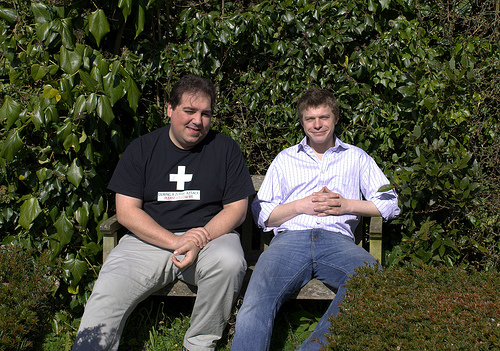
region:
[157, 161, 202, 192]
cross on mans shirt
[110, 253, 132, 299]
man wearing light grey jeans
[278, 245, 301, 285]
man wearing light blue jeans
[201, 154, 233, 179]
man wearing blue shirt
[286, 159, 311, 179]
man wearing striped shirt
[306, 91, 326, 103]
man hair is brown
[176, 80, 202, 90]
man hair is black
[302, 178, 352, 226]
mans hands are folded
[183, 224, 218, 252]
mans hand on wrist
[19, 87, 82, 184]
trees surronding men on bench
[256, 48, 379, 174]
man with short dark hair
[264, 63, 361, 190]
man with striped dress shirt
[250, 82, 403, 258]
man with his fingers crossed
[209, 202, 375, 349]
man wearing blue jeans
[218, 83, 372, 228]
man wearing a big smile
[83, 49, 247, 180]
man with his eyes closed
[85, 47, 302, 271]
man wearing a black tee shirt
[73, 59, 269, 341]
man holding his wrist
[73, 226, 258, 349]
man wearing gray pants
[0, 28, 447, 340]
several green shrubs in the background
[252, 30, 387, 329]
a man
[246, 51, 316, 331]
a man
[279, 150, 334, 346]
a man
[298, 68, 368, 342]
a man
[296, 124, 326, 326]
a man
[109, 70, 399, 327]
Two men sitting on bench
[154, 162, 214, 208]
Cross and line are white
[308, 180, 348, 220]
Hands are classed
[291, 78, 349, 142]
Face is grimacing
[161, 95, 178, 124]
Right ear is white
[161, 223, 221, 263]
Holding left wrist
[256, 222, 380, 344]
Jeans are blue and faded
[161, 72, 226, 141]
Man's face is white and pudgy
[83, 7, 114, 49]
Leaf is green and pointy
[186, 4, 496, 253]
Bush in background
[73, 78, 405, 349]
two men sitting on a bench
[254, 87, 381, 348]
man folding his hands on his belly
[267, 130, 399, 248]
man wearing a white shirt with blue stripes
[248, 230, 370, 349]
blue jeans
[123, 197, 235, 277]
man holding his wrist with his hand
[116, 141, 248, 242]
man wearing a black shirt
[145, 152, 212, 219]
white logo of a cross on a black shirt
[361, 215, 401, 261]
arm of a green bench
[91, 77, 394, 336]
two guys sitting next to each other